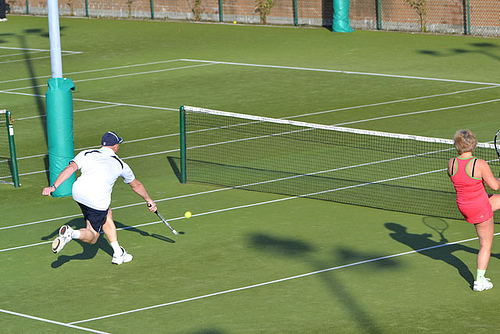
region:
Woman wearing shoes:
[471, 274, 496, 293]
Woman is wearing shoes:
[470, 272, 494, 294]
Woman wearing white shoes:
[466, 273, 491, 290]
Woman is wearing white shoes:
[470, 276, 495, 292]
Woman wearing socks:
[472, 262, 487, 277]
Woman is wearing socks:
[470, 265, 485, 285]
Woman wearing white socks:
[471, 262, 488, 282]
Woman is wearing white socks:
[471, 262, 488, 280]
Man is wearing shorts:
[72, 195, 119, 232]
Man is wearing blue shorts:
[70, 192, 111, 232]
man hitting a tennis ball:
[32, 127, 200, 268]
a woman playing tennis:
[441, 115, 494, 297]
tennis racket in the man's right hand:
[150, 196, 186, 236]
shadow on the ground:
[386, 207, 499, 283]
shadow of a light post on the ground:
[241, 228, 395, 332]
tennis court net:
[175, 101, 499, 219]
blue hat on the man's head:
[99, 126, 124, 146]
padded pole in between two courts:
[44, 68, 79, 198]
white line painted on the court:
[60, 232, 479, 328]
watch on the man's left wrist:
[48, 183, 59, 189]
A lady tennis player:
[436, 113, 498, 285]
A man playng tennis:
[21, 111, 198, 278]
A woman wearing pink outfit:
[446, 150, 499, 221]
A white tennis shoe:
[469, 256, 496, 301]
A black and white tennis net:
[179, 105, 434, 217]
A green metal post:
[169, 107, 194, 179]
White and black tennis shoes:
[40, 223, 132, 275]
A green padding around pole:
[31, 63, 86, 202]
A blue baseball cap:
[93, 121, 129, 152]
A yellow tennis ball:
[148, 197, 212, 251]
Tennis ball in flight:
[181, 207, 200, 224]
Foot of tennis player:
[109, 248, 135, 265]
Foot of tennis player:
[48, 223, 75, 255]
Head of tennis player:
[100, 129, 125, 152]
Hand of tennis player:
[37, 185, 59, 198]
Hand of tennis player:
[144, 200, 160, 213]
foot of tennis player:
[472, 270, 496, 292]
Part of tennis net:
[220, 128, 268, 162]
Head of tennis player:
[451, 126, 476, 154]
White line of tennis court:
[176, 53, 228, 70]